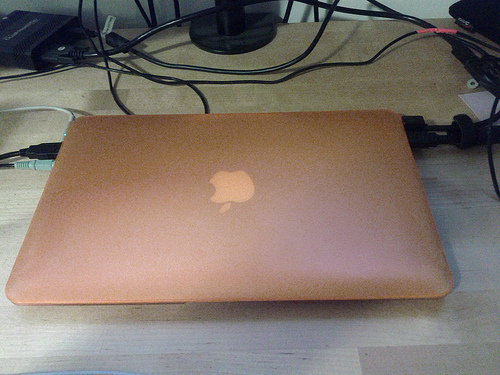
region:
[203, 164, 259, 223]
Apple symbol on a closed laptop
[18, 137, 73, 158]
Black USB cable in a laptop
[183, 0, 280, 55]
Monitor stand behind a laptop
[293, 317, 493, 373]
Wooden panel in a table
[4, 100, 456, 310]
Rose colored laptop on a desk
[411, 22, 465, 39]
Red sticker on a black cord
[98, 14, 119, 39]
White tag on a cord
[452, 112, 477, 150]
Velco strap on a cord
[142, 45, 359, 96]
Black cords on a desk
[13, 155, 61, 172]
Green plug in a laptop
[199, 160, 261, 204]
this is an apple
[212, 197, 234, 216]
this is a leaf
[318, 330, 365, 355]
this is white wood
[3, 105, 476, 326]
this is a laptop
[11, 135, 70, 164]
this is a usb cable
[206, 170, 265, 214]
this is a logo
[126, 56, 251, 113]
these are black cables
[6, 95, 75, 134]
this is a white cable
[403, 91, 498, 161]
these are computer cables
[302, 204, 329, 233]
this is the color brown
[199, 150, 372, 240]
Apple logo on the laptop.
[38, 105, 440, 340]
Laptop on the table.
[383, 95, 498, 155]
Cords on the laptop.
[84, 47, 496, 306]
Table with cords on it.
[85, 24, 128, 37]
Tag on the cord.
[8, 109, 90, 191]
Cords inserted in the laptop.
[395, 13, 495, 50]
Red tape on the cord.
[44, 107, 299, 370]
Gold laptop with apple logo on it.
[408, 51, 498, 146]
Paper on the table.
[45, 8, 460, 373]
Wood table with laptop.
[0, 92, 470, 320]
the brand of laptop is Apple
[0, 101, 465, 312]
laptop has rectangular shape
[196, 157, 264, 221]
a logotype on a laptop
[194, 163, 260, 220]
apple logotype has bite on one side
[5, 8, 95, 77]
a black box with wires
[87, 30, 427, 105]
wires behind a computer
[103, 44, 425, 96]
wires are black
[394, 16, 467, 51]
a wire is wrapped with pink seal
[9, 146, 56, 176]
a wire is plug on computer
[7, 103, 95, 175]
wires pluged on computer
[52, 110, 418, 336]
Pink laptop on table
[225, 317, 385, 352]
White cloth on table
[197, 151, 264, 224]
apple sign on laptop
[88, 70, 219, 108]
black wires behind laptop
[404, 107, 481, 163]
Bulky laptop extension plugs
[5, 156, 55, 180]
Green audio extension plug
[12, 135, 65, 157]
Black usb extension plug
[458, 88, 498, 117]
White paper on table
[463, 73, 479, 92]
White button on table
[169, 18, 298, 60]
bottom of black stand